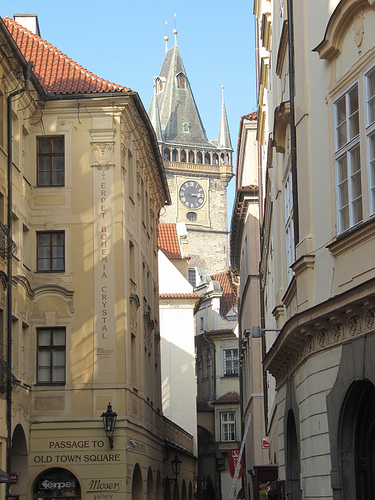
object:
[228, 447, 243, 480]
banner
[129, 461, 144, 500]
arch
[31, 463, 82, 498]
arch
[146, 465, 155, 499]
arch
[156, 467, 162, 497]
arch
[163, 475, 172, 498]
arch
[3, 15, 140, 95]
roof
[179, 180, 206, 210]
clock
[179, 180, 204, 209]
face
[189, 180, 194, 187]
numbers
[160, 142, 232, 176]
archways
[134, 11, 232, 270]
clock tower